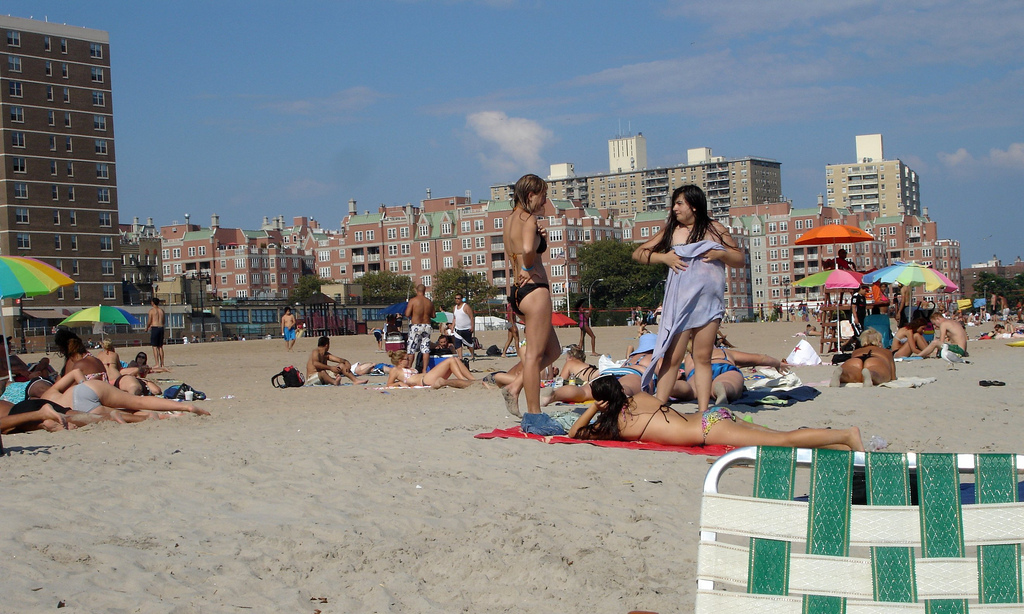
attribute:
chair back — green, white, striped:
[602, 402, 1004, 567]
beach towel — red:
[472, 368, 807, 477]